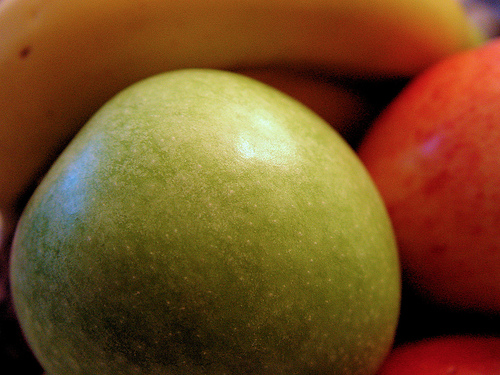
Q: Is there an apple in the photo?
A: Yes, there are apples.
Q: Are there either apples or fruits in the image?
A: Yes, there are apples.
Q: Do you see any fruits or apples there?
A: Yes, there are apples.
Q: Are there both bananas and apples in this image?
A: Yes, there are both apples and bananas.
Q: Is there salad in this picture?
A: No, there is no salad.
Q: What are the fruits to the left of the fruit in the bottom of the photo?
A: The fruits are apples.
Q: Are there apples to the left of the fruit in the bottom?
A: Yes, there are apples to the left of the fruit.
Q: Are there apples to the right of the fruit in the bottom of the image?
A: No, the apples are to the left of the fruit.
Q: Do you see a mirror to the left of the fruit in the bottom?
A: No, there are apples to the left of the fruit.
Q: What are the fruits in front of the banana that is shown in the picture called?
A: The fruits are apples.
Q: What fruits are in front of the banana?
A: The fruits are apples.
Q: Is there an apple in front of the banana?
A: Yes, there are apples in front of the banana.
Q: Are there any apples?
A: Yes, there is an apple.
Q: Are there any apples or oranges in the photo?
A: Yes, there is an apple.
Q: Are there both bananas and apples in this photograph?
A: Yes, there are both an apple and a banana.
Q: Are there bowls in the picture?
A: No, there are no bowls.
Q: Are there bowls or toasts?
A: No, there are no bowls or toasts.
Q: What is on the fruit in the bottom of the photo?
A: The apple is on the fruit.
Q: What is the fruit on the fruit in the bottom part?
A: The fruit is an apple.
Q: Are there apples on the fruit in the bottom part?
A: Yes, there is an apple on the fruit.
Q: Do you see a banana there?
A: Yes, there is a banana.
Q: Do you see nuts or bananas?
A: Yes, there is a banana.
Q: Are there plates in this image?
A: No, there are no plates.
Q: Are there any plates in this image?
A: No, there are no plates.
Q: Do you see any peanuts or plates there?
A: No, there are no plates or peanuts.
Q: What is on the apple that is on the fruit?
A: The banana is on the apple.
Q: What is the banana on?
A: The banana is on the apple.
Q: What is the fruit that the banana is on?
A: The fruit is an apple.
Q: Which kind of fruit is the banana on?
A: The banana is on the apple.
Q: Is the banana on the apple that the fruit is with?
A: Yes, the banana is on the apple.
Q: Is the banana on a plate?
A: No, the banana is on the apple.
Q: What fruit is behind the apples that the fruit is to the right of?
A: The fruit is a banana.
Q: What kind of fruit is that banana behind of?
A: The banana is behind the apples.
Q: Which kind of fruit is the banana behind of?
A: The banana is behind the apples.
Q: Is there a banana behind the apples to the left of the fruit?
A: Yes, there is a banana behind the apples.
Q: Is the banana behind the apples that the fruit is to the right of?
A: Yes, the banana is behind the apples.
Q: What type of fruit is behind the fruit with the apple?
A: The fruit is a banana.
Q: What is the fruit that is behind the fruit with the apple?
A: The fruit is a banana.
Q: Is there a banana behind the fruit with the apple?
A: Yes, there is a banana behind the fruit.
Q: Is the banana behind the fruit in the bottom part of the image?
A: Yes, the banana is behind the fruit.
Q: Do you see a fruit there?
A: Yes, there is a fruit.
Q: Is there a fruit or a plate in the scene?
A: Yes, there is a fruit.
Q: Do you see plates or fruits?
A: Yes, there is a fruit.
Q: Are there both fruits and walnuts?
A: No, there is a fruit but no walnuts.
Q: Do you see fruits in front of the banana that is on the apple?
A: Yes, there is a fruit in front of the banana.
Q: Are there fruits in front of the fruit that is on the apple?
A: Yes, there is a fruit in front of the banana.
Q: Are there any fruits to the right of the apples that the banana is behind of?
A: Yes, there is a fruit to the right of the apples.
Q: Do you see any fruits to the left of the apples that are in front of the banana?
A: No, the fruit is to the right of the apples.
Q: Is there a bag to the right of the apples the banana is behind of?
A: No, there is a fruit to the right of the apples.